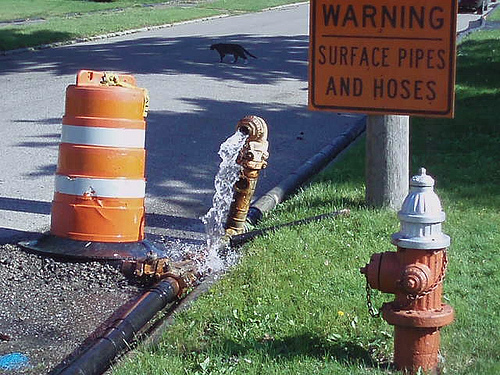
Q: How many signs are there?
A: One.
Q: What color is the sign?
A: Yellow.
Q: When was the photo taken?
A: Daytime.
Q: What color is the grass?
A: Green.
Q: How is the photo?
A: Clear.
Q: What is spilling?
A: Water.